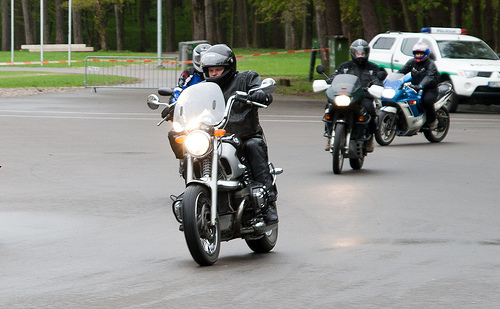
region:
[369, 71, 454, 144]
blue and silver motorcycle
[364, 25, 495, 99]
white police car with green stripe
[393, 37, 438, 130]
rider with red and white helmet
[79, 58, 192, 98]
metal gate blocking off road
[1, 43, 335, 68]
caution tape in background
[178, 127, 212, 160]
headlight on front mototcycle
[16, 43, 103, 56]
wooden bleachers in background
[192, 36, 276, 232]
rider on silver motorcycle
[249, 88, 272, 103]
glove on riders left hand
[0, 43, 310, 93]
grassy field in background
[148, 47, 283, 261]
a silver motorcycle on street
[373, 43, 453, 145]
a blue motorcycle on street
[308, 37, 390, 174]
a black motorcycle on street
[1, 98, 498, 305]
a grey paved street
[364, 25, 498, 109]
a white and green police vehicle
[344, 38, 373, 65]
a black motorcycle helmet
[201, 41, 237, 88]
a black motorcycle helmet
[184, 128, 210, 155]
a lit motorcycle headlight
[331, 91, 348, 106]
a lit motorcycle headlight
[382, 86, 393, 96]
a lit motorcycle headlight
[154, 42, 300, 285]
This is a motor bike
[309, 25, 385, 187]
This is a motor bike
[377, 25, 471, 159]
This is a motor bike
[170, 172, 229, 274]
Wheel of a motor bike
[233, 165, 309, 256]
Wheel of a motor bike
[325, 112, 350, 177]
Wheel of a motor bike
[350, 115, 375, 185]
Wheel of a motor bike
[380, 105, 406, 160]
Wheel of a motor bike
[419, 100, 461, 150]
Wheel of a motor bike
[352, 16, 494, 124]
This is a car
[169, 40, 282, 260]
man leading other motorcyclists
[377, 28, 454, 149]
last rider in line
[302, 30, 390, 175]
third rider in lane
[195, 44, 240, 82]
black helmet with visor up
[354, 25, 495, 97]
white suv in parking lot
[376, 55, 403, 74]
green stripe down side of suv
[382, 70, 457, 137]
blue and silver motorbike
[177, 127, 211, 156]
front headlight on first motorcycle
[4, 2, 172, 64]
four utility poles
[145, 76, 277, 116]
mirrors attached to handlebars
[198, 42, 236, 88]
the man is wearing a helmet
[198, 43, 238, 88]
the helmet is black in color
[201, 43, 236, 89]
the helmet is shiny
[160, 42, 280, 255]
the man is riding a motorcycle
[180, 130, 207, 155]
the headlight is on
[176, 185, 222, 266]
the tire is black in color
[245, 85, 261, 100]
the man is wearing gloves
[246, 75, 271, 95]
a rear view mirror is on the motorcycle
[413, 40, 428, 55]
the man is wearing a hemet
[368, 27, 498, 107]
the car is white in color